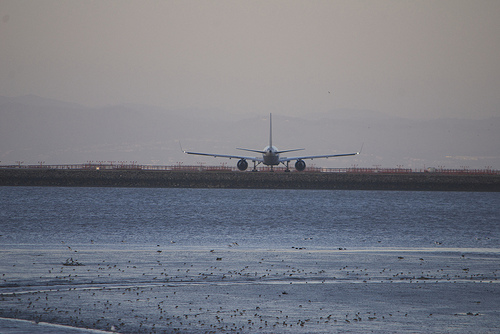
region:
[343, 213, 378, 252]
part of a water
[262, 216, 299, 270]
part of a water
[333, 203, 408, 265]
part of a water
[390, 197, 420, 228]
part of a water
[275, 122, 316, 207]
part of a planr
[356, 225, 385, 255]
edgte of a shore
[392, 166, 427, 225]
part of a shaore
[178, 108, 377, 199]
This is an airplane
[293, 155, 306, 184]
Engine of an airplane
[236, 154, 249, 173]
Engine of an airplane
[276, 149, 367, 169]
Wing of an airplane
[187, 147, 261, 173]
Wing of an airplane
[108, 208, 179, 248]
This is mass of water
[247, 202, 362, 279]
This is mass of water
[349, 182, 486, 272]
This is mass of water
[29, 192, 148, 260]
This is mass of water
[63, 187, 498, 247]
This is mass of water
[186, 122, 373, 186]
Big white plane on top of some water.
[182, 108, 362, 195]
airplane flying over water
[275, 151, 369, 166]
right wing of airplane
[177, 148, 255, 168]
left wing on airplane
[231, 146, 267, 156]
rear left tail wing on plane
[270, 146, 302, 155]
right rear tail wing on plane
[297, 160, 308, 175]
right propeller on plane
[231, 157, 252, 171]
left propellor on airplane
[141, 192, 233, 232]
large body of water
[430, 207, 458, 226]
waves in the water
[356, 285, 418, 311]
sand on the beach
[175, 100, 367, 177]
Airplane about to land.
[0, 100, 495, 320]
Airplane flying over water.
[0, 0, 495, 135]
Sky is foggy grey.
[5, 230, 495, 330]
Birds in the water.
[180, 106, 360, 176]
The airplane is flying low.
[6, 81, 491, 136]
Foggy mountains in the background.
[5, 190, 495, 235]
The water is blue.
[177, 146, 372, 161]
Lights at the tip of the wings.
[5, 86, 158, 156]
Mountains in the background are high.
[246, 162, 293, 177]
Deployed front and back wheels.